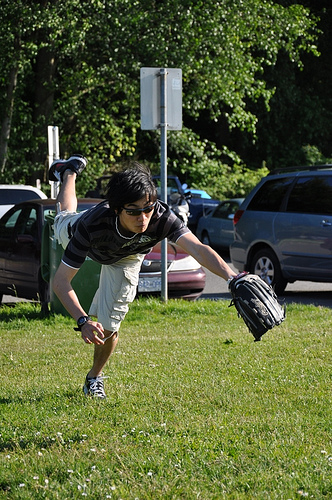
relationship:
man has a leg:
[45, 154, 283, 398] [45, 156, 85, 248]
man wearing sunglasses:
[45, 154, 283, 398] [121, 204, 154, 217]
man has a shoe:
[45, 154, 283, 398] [44, 155, 86, 182]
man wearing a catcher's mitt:
[45, 154, 283, 398] [227, 269, 285, 342]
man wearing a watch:
[45, 154, 283, 398] [73, 314, 90, 331]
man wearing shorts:
[45, 154, 283, 398] [54, 210, 147, 335]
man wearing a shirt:
[45, 154, 283, 398] [61, 200, 191, 270]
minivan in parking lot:
[229, 166, 331, 293] [0, 261, 331, 306]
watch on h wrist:
[73, 314, 90, 331] [73, 309, 90, 330]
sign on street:
[48, 125, 59, 199] [0, 261, 331, 306]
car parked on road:
[1, 199, 205, 303] [0, 261, 331, 306]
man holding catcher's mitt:
[45, 154, 283, 398] [227, 269, 285, 342]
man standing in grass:
[45, 154, 283, 398] [1, 299, 331, 499]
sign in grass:
[140, 66, 182, 131] [1, 299, 331, 499]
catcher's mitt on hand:
[227, 269, 285, 342] [228, 271, 239, 279]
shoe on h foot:
[44, 155, 86, 182] [45, 155, 87, 178]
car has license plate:
[1, 199, 205, 303] [138, 275, 162, 291]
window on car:
[1, 207, 22, 237] [1, 199, 205, 303]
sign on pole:
[140, 66, 182, 131] [158, 67, 168, 303]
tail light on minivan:
[233, 208, 244, 223] [229, 166, 331, 293]